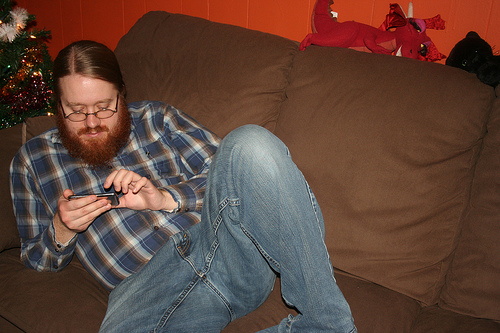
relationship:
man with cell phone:
[35, 39, 320, 307] [69, 187, 127, 223]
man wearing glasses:
[35, 39, 320, 307] [61, 98, 125, 126]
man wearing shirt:
[35, 39, 320, 307] [47, 144, 86, 191]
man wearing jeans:
[35, 39, 320, 307] [241, 145, 288, 216]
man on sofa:
[35, 39, 320, 307] [175, 24, 264, 104]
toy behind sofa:
[311, 2, 430, 55] [175, 24, 264, 104]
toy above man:
[311, 2, 430, 55] [35, 39, 320, 307]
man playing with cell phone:
[35, 39, 320, 307] [69, 187, 127, 223]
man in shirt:
[35, 39, 320, 307] [47, 144, 86, 191]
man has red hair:
[35, 39, 320, 307] [58, 35, 108, 77]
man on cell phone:
[35, 39, 320, 307] [69, 187, 127, 223]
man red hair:
[35, 39, 320, 307] [58, 35, 108, 77]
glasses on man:
[61, 98, 125, 126] [35, 39, 320, 307]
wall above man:
[73, 5, 127, 35] [35, 39, 320, 307]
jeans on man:
[241, 145, 288, 216] [35, 39, 320, 307]